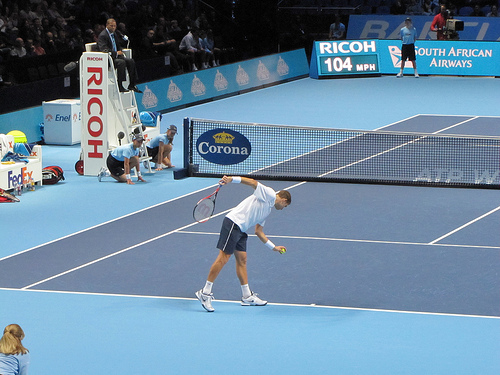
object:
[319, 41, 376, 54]
advertisement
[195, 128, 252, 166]
sign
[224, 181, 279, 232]
shirt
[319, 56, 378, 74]
display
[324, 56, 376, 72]
104 mph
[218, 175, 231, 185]
hand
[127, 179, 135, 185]
hand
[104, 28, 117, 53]
shirt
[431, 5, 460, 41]
man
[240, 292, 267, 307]
tennis shoe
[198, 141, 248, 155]
letters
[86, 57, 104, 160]
logo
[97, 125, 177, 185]
people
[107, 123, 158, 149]
seat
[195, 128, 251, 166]
advertisement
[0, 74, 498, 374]
court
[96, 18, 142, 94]
man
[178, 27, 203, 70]
spectator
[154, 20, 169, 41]
spectator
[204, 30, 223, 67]
spectator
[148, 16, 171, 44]
spectator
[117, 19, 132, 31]
spectator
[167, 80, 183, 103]
bleacher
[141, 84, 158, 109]
bleacher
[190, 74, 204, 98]
bleacher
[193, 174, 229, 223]
racket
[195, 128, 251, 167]
logo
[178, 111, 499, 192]
tennis net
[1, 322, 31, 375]
woman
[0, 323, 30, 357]
hair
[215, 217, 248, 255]
shorts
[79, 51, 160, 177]
chair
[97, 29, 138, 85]
suit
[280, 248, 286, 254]
ball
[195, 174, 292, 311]
man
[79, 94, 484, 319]
event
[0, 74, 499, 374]
tennis court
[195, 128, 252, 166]
brand logo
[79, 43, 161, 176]
elevated seat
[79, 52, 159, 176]
base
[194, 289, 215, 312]
shoes